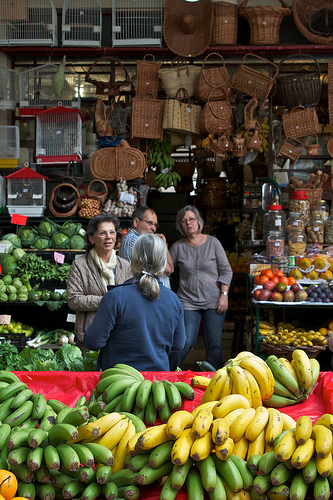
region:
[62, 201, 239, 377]
a group of people in a market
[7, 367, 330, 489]
group of ripe and unripe bananas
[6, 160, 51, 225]
a white bird cage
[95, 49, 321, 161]
hanging wicker purses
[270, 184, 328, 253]
group of plastic containers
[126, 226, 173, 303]
hair clip in womans hair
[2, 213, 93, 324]
a group of different green vegetables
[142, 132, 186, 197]
green bananas hanging from ceiling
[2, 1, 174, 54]
three bird cages on a shelf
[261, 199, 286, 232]
plastic containter with a red lid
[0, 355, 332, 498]
A counter displaying bananas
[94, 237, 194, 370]
A woman wearing a blue jacket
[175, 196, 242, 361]
A woman wearing a gray shirt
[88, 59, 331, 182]
A bunch of hanging baskets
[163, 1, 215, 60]
A brown straw hat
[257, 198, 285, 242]
An empty jar with red top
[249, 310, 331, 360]
A basket of bananas under a table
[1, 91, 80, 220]
Birdcages hanging on wall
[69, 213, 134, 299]
A woman wearing a beige scarf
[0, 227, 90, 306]
A table of vegetables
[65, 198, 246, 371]
Four patrons chat market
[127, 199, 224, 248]
Both people wear eyeglasses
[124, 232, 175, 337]
Gray hair pulled ponytail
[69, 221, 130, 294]
White scarf wrapped neck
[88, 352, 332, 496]
Yellow ripe green not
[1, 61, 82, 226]
Bird cages hung ceiling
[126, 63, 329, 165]
All types wicker baskets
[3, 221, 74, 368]
Green produce packs shelves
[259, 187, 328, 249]
Delicacies red topped jars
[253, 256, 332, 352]
Colorful fruit await customers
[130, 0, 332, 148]
woven baskets hung high on the wall for sale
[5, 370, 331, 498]
plantains displayed for sale on a table covered in red plastic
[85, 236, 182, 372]
grey haired shop owner talking to customers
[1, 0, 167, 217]
a large selection of bird cages for sale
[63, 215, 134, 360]
customer talking to shop keeper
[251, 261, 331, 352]
mangos , oranges, lemons and other fruit neatly stacked and for sale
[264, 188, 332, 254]
closed jars of candy and such for sale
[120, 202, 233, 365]
couple checking out the goods for sale at this shop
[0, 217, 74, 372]
green vegatables stacked and for sale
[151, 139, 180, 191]
green finger bananas hung from roof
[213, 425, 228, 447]
black spot on yellow banana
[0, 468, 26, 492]
stem of yellow orange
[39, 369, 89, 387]
red covering on surface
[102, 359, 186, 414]
bunch of green bananas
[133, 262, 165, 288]
black holder in woman's hair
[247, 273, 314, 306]
juicy mangoes stacked on shelf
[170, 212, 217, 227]
silver glasses on woman's face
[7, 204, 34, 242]
small orange square sign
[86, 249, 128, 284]
white scarf around woman's neck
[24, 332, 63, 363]
bunch of green and white scallion